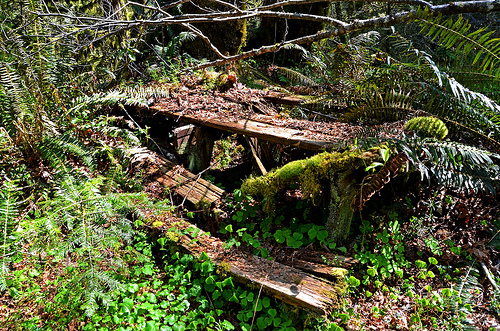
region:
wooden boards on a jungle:
[79, 80, 460, 312]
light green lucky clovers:
[120, 207, 467, 329]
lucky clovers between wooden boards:
[212, 200, 332, 267]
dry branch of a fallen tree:
[44, 0, 493, 77]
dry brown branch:
[43, 1, 498, 76]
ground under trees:
[342, 168, 497, 329]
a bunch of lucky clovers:
[85, 214, 345, 329]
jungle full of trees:
[4, 2, 494, 329]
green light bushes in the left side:
[0, 1, 136, 209]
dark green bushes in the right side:
[299, 2, 496, 208]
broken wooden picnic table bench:
[117, 147, 369, 320]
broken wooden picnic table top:
[133, 80, 400, 150]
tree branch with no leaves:
[31, 4, 491, 33]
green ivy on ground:
[74, 245, 290, 328]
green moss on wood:
[226, 140, 414, 198]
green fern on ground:
[7, 122, 93, 239]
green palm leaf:
[416, 13, 498, 70]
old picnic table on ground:
[107, 76, 392, 318]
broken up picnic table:
[93, 72, 421, 315]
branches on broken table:
[33, 4, 488, 155]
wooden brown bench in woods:
[162, 77, 305, 154]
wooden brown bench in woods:
[135, 160, 241, 265]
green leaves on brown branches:
[61, 272, 142, 318]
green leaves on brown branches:
[147, 292, 191, 320]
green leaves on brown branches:
[12, 220, 59, 280]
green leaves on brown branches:
[54, 174, 91, 225]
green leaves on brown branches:
[76, 77, 124, 146]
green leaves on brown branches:
[230, 220, 300, 268]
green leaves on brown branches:
[326, 229, 396, 269]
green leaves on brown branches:
[368, 236, 462, 293]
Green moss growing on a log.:
[242, 156, 367, 221]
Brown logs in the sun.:
[159, 78, 351, 158]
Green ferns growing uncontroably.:
[412, 11, 498, 114]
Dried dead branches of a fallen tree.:
[35, 8, 494, 55]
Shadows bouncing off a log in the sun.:
[217, 229, 326, 297]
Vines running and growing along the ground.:
[101, 283, 248, 329]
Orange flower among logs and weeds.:
[220, 68, 240, 91]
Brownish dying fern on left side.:
[14, 18, 51, 191]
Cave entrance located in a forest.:
[130, 2, 312, 65]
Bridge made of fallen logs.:
[115, 87, 370, 136]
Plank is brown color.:
[141, 84, 355, 285]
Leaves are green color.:
[91, 247, 208, 329]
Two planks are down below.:
[142, 160, 322, 312]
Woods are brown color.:
[110, 3, 405, 61]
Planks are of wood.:
[157, 76, 383, 176]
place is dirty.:
[27, 37, 430, 270]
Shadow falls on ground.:
[42, 30, 473, 330]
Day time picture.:
[43, 21, 428, 277]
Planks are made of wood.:
[200, 82, 330, 187]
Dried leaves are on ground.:
[10, 250, 105, 320]